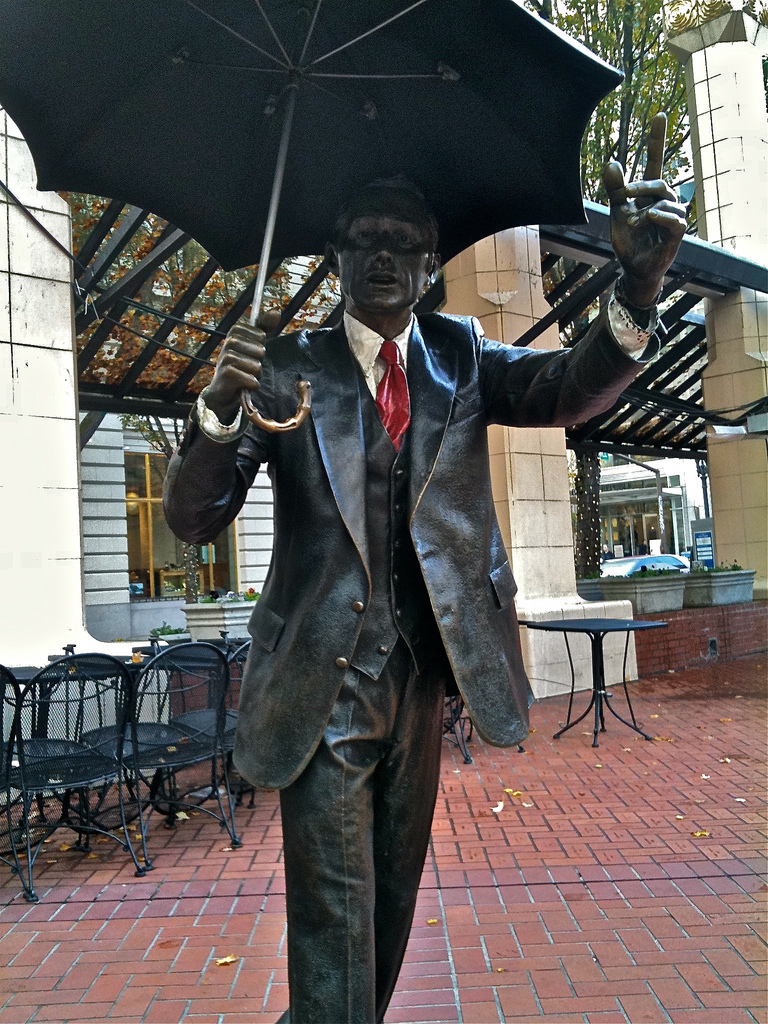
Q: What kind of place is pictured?
A: It is a sidewalk.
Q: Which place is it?
A: It is a sidewalk.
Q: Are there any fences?
A: No, there are no fences.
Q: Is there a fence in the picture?
A: No, there are no fences.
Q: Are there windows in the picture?
A: Yes, there is a window.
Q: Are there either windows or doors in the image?
A: Yes, there is a window.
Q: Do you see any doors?
A: No, there are no doors.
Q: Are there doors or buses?
A: No, there are no doors or buses.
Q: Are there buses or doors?
A: No, there are no doors or buses.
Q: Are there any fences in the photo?
A: No, there are no fences.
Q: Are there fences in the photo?
A: No, there are no fences.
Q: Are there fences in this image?
A: No, there are no fences.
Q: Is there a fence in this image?
A: No, there are no fences.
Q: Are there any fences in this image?
A: No, there are no fences.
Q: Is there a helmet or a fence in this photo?
A: No, there are no fences or helmets.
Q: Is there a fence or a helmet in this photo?
A: No, there are no fences or helmets.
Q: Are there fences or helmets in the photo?
A: No, there are no fences or helmets.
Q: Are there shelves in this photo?
A: No, there are no shelves.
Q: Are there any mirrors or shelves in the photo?
A: No, there are no shelves or mirrors.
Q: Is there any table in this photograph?
A: Yes, there is a table.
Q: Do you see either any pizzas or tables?
A: Yes, there is a table.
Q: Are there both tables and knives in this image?
A: No, there is a table but no knives.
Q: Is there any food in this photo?
A: No, there is no food.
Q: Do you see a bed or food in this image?
A: No, there are no food or beds.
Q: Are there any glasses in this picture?
A: No, there are no glasses.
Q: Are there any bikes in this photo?
A: No, there are no bikes.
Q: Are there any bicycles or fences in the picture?
A: No, there are no bicycles or fences.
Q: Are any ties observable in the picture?
A: Yes, there is a tie.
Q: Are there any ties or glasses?
A: Yes, there is a tie.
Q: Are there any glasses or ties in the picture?
A: Yes, there is a tie.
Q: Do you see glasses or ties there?
A: Yes, there is a tie.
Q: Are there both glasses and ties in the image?
A: No, there is a tie but no glasses.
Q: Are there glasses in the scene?
A: No, there are no glasses.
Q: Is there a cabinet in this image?
A: No, there are no cabinets.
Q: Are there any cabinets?
A: No, there are no cabinets.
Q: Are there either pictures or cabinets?
A: No, there are no cabinets or pictures.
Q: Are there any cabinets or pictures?
A: No, there are no cabinets or pictures.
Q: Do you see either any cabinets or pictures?
A: No, there are no cabinets or pictures.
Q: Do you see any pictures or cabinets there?
A: No, there are no cabinets or pictures.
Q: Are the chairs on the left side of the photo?
A: Yes, the chairs are on the left of the image.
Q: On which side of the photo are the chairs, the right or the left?
A: The chairs are on the left of the image.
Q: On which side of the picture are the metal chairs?
A: The chairs are on the left of the image.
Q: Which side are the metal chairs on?
A: The chairs are on the left of the image.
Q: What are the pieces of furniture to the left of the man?
A: The pieces of furniture are chairs.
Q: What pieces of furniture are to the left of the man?
A: The pieces of furniture are chairs.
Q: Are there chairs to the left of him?
A: Yes, there are chairs to the left of the man.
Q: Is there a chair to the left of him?
A: Yes, there are chairs to the left of the man.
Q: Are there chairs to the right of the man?
A: No, the chairs are to the left of the man.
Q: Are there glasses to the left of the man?
A: No, there are chairs to the left of the man.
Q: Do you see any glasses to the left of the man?
A: No, there are chairs to the left of the man.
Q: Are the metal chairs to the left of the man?
A: Yes, the chairs are to the left of the man.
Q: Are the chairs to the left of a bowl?
A: No, the chairs are to the left of the man.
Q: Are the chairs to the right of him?
A: No, the chairs are to the left of the man.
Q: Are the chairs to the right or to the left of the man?
A: The chairs are to the left of the man.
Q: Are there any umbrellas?
A: Yes, there is an umbrella.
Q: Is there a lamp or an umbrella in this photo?
A: Yes, there is an umbrella.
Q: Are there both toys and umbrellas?
A: No, there is an umbrella but no toys.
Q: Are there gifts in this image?
A: No, there are no gifts.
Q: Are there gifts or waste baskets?
A: No, there are no gifts or waste baskets.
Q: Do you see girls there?
A: No, there are no girls.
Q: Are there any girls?
A: No, there are no girls.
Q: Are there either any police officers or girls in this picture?
A: No, there are no girls or police officers.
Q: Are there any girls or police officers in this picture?
A: No, there are no girls or police officers.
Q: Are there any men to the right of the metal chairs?
A: Yes, there is a man to the right of the chairs.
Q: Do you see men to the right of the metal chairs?
A: Yes, there is a man to the right of the chairs.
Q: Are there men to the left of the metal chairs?
A: No, the man is to the right of the chairs.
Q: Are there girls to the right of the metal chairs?
A: No, there is a man to the right of the chairs.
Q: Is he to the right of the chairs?
A: Yes, the man is to the right of the chairs.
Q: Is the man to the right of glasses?
A: No, the man is to the right of the chairs.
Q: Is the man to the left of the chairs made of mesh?
A: No, the man is to the right of the chairs.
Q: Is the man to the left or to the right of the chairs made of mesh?
A: The man is to the right of the chairs.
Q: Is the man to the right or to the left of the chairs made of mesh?
A: The man is to the right of the chairs.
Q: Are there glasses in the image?
A: No, there are no glasses.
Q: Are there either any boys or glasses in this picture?
A: No, there are no glasses or boys.